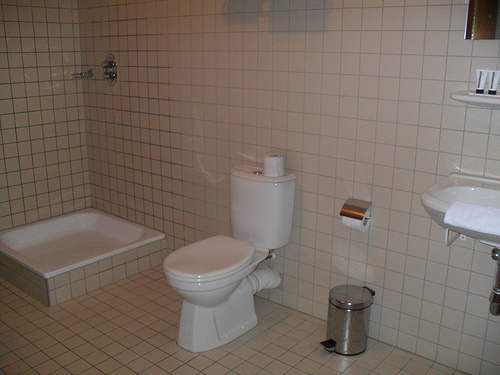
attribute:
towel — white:
[440, 190, 500, 245]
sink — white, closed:
[418, 165, 500, 324]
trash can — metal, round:
[318, 279, 381, 362]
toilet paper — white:
[338, 213, 373, 235]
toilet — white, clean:
[160, 160, 305, 358]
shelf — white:
[449, 88, 500, 114]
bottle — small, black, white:
[472, 66, 491, 98]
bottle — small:
[486, 67, 500, 98]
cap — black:
[470, 87, 485, 99]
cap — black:
[486, 88, 499, 98]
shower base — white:
[2, 199, 170, 286]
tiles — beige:
[0, 233, 175, 310]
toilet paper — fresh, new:
[256, 150, 291, 180]